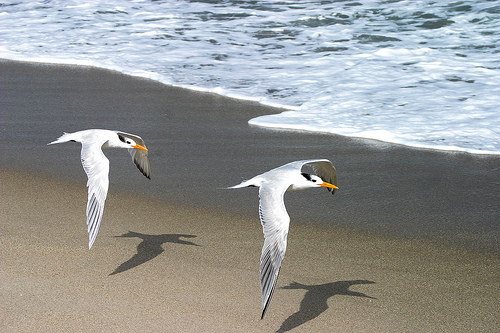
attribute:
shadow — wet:
[108, 222, 200, 275]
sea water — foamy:
[1, 2, 497, 162]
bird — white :
[220, 148, 362, 318]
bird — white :
[49, 105, 166, 235]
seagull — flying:
[35, 100, 192, 260]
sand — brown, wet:
[36, 17, 78, 60]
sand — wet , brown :
[4, 56, 499, 254]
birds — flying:
[39, 115, 342, 327]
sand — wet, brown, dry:
[3, 60, 499, 330]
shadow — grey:
[273, 276, 381, 330]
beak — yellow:
[319, 181, 339, 193]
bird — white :
[45, 125, 153, 253]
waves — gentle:
[2, 4, 496, 158]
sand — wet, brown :
[105, 88, 190, 128]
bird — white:
[213, 155, 344, 329]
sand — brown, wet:
[331, 265, 451, 331]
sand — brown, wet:
[191, 121, 495, 238]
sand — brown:
[45, 260, 145, 333]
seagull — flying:
[224, 154, 350, 320]